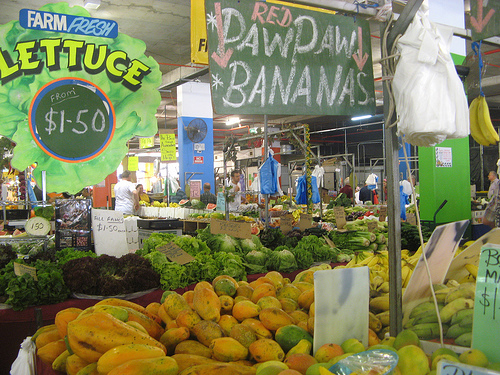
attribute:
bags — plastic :
[394, 29, 472, 140]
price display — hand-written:
[24, 80, 122, 159]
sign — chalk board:
[205, 0, 390, 126]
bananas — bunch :
[328, 228, 461, 307]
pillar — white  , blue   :
[388, 23, 474, 142]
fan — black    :
[188, 111, 204, 148]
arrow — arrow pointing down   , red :
[210, 2, 237, 72]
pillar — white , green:
[2, 6, 167, 187]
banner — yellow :
[181, 3, 345, 72]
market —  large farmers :
[4, 9, 484, 369]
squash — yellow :
[71, 301, 288, 363]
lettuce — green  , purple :
[65, 250, 155, 289]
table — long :
[118, 196, 378, 262]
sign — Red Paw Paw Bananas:
[205, 3, 381, 115]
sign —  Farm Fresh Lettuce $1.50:
[3, 4, 165, 189]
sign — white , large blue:
[174, 82, 218, 189]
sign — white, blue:
[170, 80, 220, 193]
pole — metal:
[368, 16, 418, 336]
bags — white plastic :
[389, 10, 474, 142]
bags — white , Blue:
[396, 10, 473, 149]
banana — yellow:
[458, 96, 483, 154]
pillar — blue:
[171, 77, 221, 176]